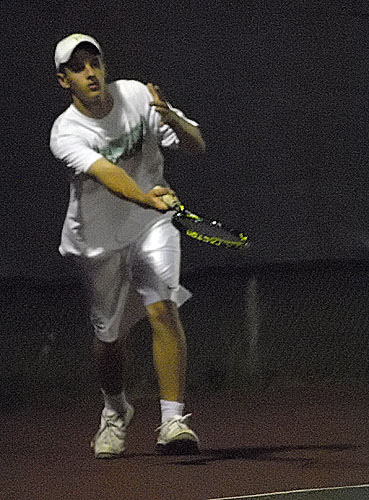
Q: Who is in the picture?
A: A man.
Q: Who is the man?
A: A tennis player.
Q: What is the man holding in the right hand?
A: A tennis racket.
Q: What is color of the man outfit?
A: White.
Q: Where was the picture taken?
A: At the tennis court.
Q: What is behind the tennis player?
A: A metal fence.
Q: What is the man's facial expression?
A: Concentrated.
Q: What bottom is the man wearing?
A: Shorts.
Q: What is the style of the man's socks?
A: Crew style.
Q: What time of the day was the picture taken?
A: Evening.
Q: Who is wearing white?
A: The kid.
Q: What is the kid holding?
A: A racket.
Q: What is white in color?
A: The shorts.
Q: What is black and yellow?
A: Tennis racket.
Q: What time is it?
A: Evening.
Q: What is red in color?
A: The floor.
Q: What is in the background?
A: A fence.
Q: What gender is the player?
A: Male.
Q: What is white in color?
A: Shoes.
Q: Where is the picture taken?
A: A tennis court.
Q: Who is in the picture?
A: A man.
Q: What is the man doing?
A: Playing tennis.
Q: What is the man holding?
A: A tennis racket.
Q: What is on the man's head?
A: A white cap.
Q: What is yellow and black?
A: A tennis racket.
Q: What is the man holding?
A: A tennis racquet.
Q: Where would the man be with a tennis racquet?
A: At a tennis court.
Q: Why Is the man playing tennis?
A: Because it's fun.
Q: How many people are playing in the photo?
A: One.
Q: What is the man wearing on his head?
A: A hat.